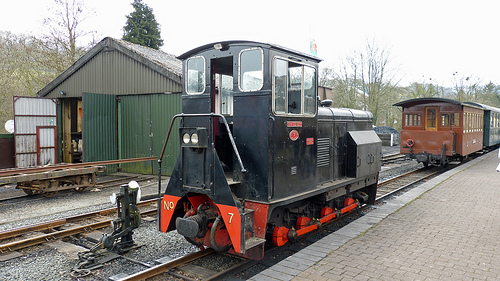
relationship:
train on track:
[165, 42, 380, 255] [106, 167, 448, 279]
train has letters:
[165, 42, 380, 255] [162, 196, 175, 213]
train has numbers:
[165, 42, 380, 255] [225, 210, 235, 222]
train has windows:
[165, 42, 380, 255] [185, 46, 270, 95]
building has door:
[38, 40, 183, 182] [14, 94, 57, 165]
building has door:
[38, 40, 183, 182] [82, 91, 117, 172]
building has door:
[38, 40, 183, 182] [119, 94, 153, 174]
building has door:
[38, 40, 183, 182] [151, 93, 183, 175]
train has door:
[165, 42, 380, 255] [210, 60, 231, 184]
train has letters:
[165, 42, 380, 255] [286, 116, 304, 142]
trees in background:
[0, 10, 498, 139] [1, 6, 496, 142]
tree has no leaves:
[48, 0, 97, 74] [78, 25, 97, 38]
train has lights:
[165, 42, 380, 255] [179, 128, 202, 146]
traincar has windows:
[394, 95, 499, 171] [404, 111, 496, 135]